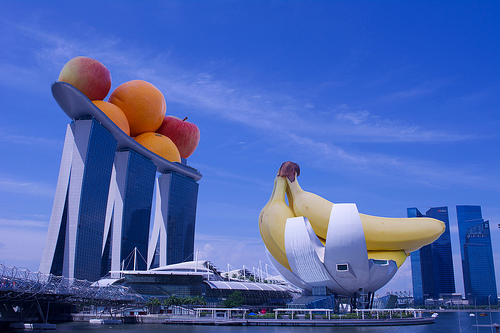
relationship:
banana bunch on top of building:
[259, 159, 443, 279] [271, 203, 395, 300]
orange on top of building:
[110, 81, 166, 132] [36, 119, 120, 286]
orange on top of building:
[91, 96, 130, 135] [271, 203, 395, 300]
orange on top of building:
[133, 131, 182, 164] [36, 119, 120, 286]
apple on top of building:
[59, 56, 109, 104] [36, 119, 120, 286]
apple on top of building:
[158, 115, 200, 157] [36, 119, 120, 286]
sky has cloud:
[1, 3, 495, 298] [31, 21, 475, 196]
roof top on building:
[282, 213, 330, 290] [271, 203, 395, 300]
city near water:
[3, 83, 496, 309] [2, 284, 499, 332]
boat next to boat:
[430, 310, 439, 320] [469, 311, 476, 319]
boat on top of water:
[430, 310, 439, 320] [2, 284, 499, 332]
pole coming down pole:
[132, 246, 138, 271] [135, 247, 154, 269]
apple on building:
[59, 56, 109, 104] [36, 119, 120, 286]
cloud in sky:
[31, 21, 475, 196] [1, 3, 495, 298]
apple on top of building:
[158, 115, 200, 157] [271, 203, 395, 300]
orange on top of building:
[91, 96, 130, 135] [36, 119, 120, 286]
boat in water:
[430, 310, 439, 320] [2, 284, 499, 332]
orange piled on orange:
[91, 96, 130, 135] [110, 81, 166, 132]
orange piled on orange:
[133, 131, 182, 164] [110, 81, 166, 132]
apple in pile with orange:
[59, 56, 109, 104] [110, 81, 166, 132]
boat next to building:
[429, 311, 439, 318] [408, 201, 456, 307]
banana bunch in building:
[259, 159, 443, 279] [271, 203, 395, 300]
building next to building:
[48, 118, 110, 285] [102, 146, 152, 277]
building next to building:
[36, 119, 120, 286] [152, 169, 198, 267]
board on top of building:
[53, 82, 199, 181] [36, 119, 120, 286]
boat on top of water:
[469, 311, 476, 319] [2, 284, 499, 332]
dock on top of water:
[16, 322, 55, 329] [2, 284, 499, 332]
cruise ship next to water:
[87, 263, 282, 309] [2, 284, 499, 332]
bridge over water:
[3, 268, 134, 320] [2, 284, 499, 332]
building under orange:
[48, 118, 110, 285] [110, 81, 166, 132]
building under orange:
[102, 146, 152, 277] [110, 81, 166, 132]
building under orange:
[152, 169, 198, 267] [110, 81, 166, 132]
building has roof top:
[271, 203, 395, 300] [282, 213, 330, 290]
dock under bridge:
[16, 322, 55, 329] [3, 268, 134, 320]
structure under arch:
[258, 307, 266, 316] [207, 274, 296, 295]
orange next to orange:
[110, 81, 166, 132] [91, 96, 130, 135]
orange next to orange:
[91, 96, 130, 135] [133, 131, 182, 164]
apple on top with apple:
[59, 56, 109, 104] [158, 115, 200, 157]